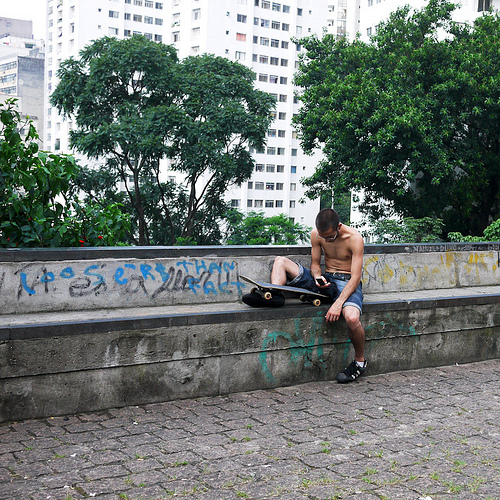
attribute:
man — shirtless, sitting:
[244, 208, 377, 384]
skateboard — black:
[238, 274, 326, 308]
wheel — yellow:
[262, 289, 274, 303]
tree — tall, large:
[47, 30, 278, 245]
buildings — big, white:
[1, 0, 498, 245]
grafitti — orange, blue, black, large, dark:
[5, 256, 238, 309]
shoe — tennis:
[240, 287, 287, 308]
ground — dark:
[3, 357, 499, 499]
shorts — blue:
[290, 260, 366, 311]